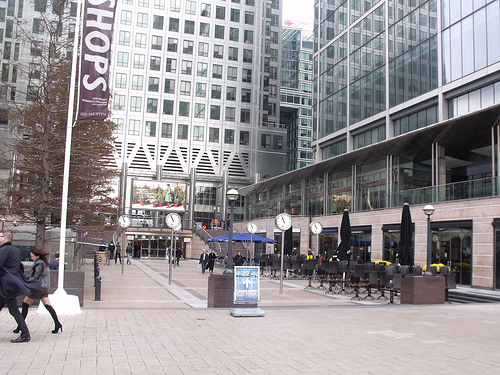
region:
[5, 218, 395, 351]
Many people in the square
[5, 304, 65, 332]
she has knee high boots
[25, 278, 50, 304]
she is wearing a skirt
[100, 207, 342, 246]
there are five clocks on posts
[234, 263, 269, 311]
The sign is light blue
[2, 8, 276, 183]
the building has many windows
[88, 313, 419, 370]
the floor is tiled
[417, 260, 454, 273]
the flowers are yellow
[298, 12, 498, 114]
the glass is reflective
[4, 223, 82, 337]
a man and woman walk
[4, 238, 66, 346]
this is a person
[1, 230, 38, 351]
this is a person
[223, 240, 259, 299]
this is a person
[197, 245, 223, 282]
this is a person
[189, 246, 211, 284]
this is a person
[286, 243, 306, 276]
this is a person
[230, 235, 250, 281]
this is a person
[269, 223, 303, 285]
this is a person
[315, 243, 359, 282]
this is a person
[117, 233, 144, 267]
this is a person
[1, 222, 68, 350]
people walking on street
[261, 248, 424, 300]
seating area outside of building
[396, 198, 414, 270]
umbrella for seating area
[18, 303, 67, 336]
knee high boots on woman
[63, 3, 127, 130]
banner hanging from pole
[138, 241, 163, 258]
doors to a building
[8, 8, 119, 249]
tree in the center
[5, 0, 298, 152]
building with many rooms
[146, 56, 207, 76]
windows in the building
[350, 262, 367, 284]
a seat in the outdoor area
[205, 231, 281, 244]
Two blue opened umbrellas.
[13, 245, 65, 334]
A girl with blowing brown hair and black stockings.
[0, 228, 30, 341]
A man in a long black coat and black shoes walking by a girl in black heals.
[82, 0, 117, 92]
SHOPS in white coloron a brown banner.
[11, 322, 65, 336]
Black high heels on a woman walking by a man.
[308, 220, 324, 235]
The most right white and black clock.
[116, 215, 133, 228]
The most left black and white clock.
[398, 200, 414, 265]
The first closest black closed umbrella on the right.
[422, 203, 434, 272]
A light on top of a dark colored pole to the right of a black closed umbrella.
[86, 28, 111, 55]
Round O in SHOPS on a banner.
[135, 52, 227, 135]
A building in the photo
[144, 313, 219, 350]
Cabro paving in the photo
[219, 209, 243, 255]
A pole in the photo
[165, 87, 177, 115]
Window in the photo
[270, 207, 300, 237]
Clock in the photo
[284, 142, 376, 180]
Canopy in the photo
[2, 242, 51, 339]
People walking in the photo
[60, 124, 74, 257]
A flagpost in the photo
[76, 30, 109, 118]
A flag in the air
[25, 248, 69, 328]
A lady walking